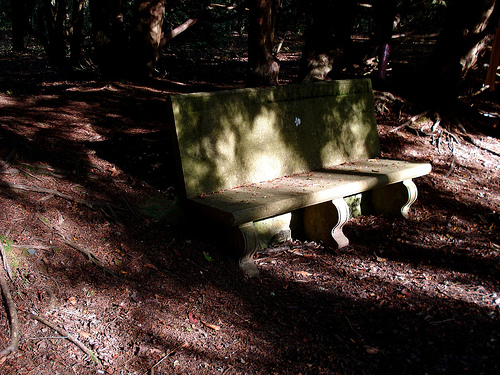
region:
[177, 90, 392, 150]
the chair has green moss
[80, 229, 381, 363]
the soil is red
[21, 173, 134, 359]
the root are above the ground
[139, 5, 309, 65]
the stems are brown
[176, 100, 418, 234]
the chair is made of stone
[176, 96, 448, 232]
the chair is illuminated by the shadow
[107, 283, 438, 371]
the ground is coverd by the dry leaves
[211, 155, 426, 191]
the chair has dirt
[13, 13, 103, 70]
the background is dark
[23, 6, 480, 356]
the photo was taken on a sunny day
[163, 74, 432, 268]
a granite bench on the ground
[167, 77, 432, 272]
the bench is grey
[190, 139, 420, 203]
leaves on the bench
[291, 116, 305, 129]
a white spot on the bench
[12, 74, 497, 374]
the ground is covered with leaves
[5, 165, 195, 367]
branches on the ground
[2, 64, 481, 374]
the ground is reddish brown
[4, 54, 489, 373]
tree shadows on the ground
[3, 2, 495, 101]
tree branches behind the fence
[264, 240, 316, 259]
a stick under the bench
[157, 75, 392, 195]
Back of stone bench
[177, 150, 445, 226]
Seat of stone bench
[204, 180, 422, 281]
Legs of stone bench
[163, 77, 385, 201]
Shadows of trees on stone bench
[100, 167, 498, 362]
Shadows of trees on ground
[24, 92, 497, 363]
Brown dirt on ground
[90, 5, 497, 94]
Brown trunks of trees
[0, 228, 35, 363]
Brown root of trees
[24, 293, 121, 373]
Brown stick on ground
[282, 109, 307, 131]
Blue flower on stone bench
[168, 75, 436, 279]
cement park bench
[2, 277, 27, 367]
tree root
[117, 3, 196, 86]
tree in the background shadows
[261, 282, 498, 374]
shadow of a tree on forest floor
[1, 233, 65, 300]
foliage on the forest floor at base of tree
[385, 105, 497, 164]
tree roots in the sunlight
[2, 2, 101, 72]
tree foliage in the shadows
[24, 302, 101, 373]
tree root in the foreground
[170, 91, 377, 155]
shadows of trees on the park bench seat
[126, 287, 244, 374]
forest floor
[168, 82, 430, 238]
a bench on the ground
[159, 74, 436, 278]
the bench is dirty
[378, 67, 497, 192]
tree roots beside the bench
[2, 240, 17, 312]
moss under a tree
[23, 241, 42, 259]
a grey rock on the ground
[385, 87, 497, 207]
a light spot on the ground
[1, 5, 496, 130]
a forest behind the bench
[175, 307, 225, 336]
leaves on the ground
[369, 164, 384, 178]
a leaf on the bench